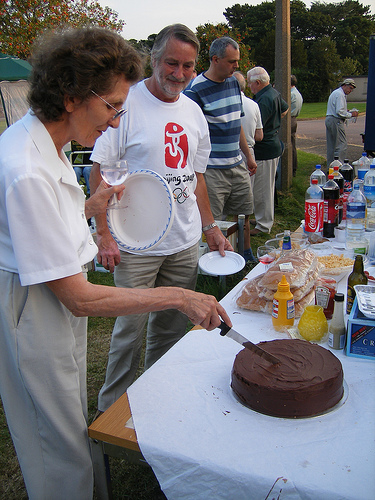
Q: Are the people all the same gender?
A: No, they are both male and female.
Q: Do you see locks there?
A: No, there are no locks.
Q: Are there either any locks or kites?
A: No, there are no locks or kites.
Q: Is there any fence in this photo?
A: No, there are no fences.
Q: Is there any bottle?
A: Yes, there is a bottle.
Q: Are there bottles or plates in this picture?
A: Yes, there is a bottle.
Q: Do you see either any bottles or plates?
A: Yes, there is a bottle.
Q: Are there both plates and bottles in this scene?
A: Yes, there are both a bottle and a plate.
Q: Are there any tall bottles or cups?
A: Yes, there is a tall bottle.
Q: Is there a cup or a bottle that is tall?
A: Yes, the bottle is tall.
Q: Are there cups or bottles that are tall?
A: Yes, the bottle is tall.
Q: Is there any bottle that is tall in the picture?
A: Yes, there is a tall bottle.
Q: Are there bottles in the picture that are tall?
A: Yes, there is a bottle that is tall.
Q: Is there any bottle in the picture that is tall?
A: Yes, there is a bottle that is tall.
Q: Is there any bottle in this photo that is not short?
A: Yes, there is a tall bottle.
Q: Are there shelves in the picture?
A: No, there are no shelves.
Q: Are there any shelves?
A: No, there are no shelves.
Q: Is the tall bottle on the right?
A: Yes, the bottle is on the right of the image.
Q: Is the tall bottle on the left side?
A: No, the bottle is on the right of the image.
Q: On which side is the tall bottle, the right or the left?
A: The bottle is on the right of the image.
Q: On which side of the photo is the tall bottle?
A: The bottle is on the right of the image.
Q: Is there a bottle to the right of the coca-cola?
A: Yes, there is a bottle to the right of the coca-cola.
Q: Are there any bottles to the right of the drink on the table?
A: Yes, there is a bottle to the right of the coca-cola.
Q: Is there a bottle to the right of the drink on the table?
A: Yes, there is a bottle to the right of the coca-cola.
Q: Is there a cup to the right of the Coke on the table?
A: No, there is a bottle to the right of the Coca Cola.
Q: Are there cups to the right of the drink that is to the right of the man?
A: No, there is a bottle to the right of the Coca Cola.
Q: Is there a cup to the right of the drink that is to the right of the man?
A: No, there is a bottle to the right of the Coca Cola.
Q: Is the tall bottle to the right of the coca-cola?
A: Yes, the bottle is to the right of the coca-cola.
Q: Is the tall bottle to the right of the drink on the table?
A: Yes, the bottle is to the right of the coca-cola.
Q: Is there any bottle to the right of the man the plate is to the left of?
A: Yes, there is a bottle to the right of the man.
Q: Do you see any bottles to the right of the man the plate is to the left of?
A: Yes, there is a bottle to the right of the man.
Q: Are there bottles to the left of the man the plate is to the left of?
A: No, the bottle is to the right of the man.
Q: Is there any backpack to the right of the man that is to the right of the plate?
A: No, there is a bottle to the right of the man.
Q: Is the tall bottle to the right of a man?
A: Yes, the bottle is to the right of a man.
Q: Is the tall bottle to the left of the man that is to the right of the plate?
A: No, the bottle is to the right of the man.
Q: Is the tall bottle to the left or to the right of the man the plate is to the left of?
A: The bottle is to the right of the man.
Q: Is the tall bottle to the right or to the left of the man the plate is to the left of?
A: The bottle is to the right of the man.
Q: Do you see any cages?
A: No, there are no cages.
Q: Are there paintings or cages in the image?
A: No, there are no cages or paintings.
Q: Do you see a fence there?
A: No, there are no fences.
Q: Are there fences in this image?
A: No, there are no fences.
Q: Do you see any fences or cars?
A: No, there are no fences or cars.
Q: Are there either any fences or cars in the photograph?
A: No, there are no fences or cars.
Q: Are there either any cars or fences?
A: No, there are no fences or cars.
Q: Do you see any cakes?
A: Yes, there is a cake.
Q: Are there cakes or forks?
A: Yes, there is a cake.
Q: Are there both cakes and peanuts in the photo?
A: No, there is a cake but no peanuts.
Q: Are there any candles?
A: No, there are no candles.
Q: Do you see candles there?
A: No, there are no candles.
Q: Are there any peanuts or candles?
A: No, there are no candles or peanuts.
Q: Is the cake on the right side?
A: Yes, the cake is on the right of the image.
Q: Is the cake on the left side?
A: No, the cake is on the right of the image.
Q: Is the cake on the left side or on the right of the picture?
A: The cake is on the right of the image.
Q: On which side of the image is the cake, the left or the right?
A: The cake is on the right of the image.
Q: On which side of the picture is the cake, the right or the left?
A: The cake is on the right of the image.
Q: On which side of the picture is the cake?
A: The cake is on the right of the image.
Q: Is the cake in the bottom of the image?
A: Yes, the cake is in the bottom of the image.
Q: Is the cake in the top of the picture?
A: No, the cake is in the bottom of the image.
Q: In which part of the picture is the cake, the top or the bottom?
A: The cake is in the bottom of the image.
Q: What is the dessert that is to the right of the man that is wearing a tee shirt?
A: The dessert is a cake.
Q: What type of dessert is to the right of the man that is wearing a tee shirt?
A: The dessert is a cake.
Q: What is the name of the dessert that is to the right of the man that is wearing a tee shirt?
A: The dessert is a cake.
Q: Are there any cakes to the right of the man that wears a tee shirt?
A: Yes, there is a cake to the right of the man.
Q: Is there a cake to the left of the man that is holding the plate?
A: No, the cake is to the right of the man.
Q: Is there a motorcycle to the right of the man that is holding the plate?
A: No, there is a cake to the right of the man.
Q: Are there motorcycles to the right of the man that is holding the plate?
A: No, there is a cake to the right of the man.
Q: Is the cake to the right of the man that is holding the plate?
A: Yes, the cake is to the right of the man.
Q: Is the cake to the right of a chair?
A: No, the cake is to the right of the man.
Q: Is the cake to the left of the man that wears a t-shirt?
A: No, the cake is to the right of the man.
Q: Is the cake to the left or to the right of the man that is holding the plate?
A: The cake is to the right of the man.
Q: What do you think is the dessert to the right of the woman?
A: The dessert is a cake.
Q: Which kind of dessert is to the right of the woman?
A: The dessert is a cake.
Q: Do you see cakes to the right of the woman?
A: Yes, there is a cake to the right of the woman.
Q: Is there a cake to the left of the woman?
A: No, the cake is to the right of the woman.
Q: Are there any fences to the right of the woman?
A: No, there is a cake to the right of the woman.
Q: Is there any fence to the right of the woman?
A: No, there is a cake to the right of the woman.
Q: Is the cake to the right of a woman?
A: Yes, the cake is to the right of a woman.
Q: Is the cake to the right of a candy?
A: No, the cake is to the right of a woman.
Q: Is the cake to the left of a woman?
A: No, the cake is to the right of a woman.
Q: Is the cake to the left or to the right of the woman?
A: The cake is to the right of the woman.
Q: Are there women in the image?
A: Yes, there is a woman.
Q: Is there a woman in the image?
A: Yes, there is a woman.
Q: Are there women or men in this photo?
A: Yes, there is a woman.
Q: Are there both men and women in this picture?
A: Yes, there are both a woman and a man.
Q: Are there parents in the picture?
A: No, there are no parents.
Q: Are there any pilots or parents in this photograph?
A: No, there are no parents or pilots.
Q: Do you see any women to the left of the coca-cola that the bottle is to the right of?
A: Yes, there is a woman to the left of the Cola.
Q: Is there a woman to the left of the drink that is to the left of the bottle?
A: Yes, there is a woman to the left of the Cola.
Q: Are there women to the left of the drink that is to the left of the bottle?
A: Yes, there is a woman to the left of the Cola.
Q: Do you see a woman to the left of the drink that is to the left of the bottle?
A: Yes, there is a woman to the left of the Cola.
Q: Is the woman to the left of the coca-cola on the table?
A: Yes, the woman is to the left of the coca-cola.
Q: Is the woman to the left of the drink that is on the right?
A: Yes, the woman is to the left of the coca-cola.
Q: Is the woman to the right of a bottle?
A: No, the woman is to the left of a bottle.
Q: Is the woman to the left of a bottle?
A: Yes, the woman is to the left of a bottle.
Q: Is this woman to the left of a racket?
A: No, the woman is to the left of a bottle.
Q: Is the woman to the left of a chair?
A: No, the woman is to the left of a man.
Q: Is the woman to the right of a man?
A: No, the woman is to the left of a man.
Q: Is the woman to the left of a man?
A: Yes, the woman is to the left of a man.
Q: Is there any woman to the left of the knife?
A: Yes, there is a woman to the left of the knife.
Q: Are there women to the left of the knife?
A: Yes, there is a woman to the left of the knife.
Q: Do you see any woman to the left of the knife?
A: Yes, there is a woman to the left of the knife.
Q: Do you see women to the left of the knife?
A: Yes, there is a woman to the left of the knife.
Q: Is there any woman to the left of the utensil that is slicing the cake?
A: Yes, there is a woman to the left of the knife.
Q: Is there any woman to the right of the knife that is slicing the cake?
A: No, the woman is to the left of the knife.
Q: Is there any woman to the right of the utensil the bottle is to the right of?
A: No, the woman is to the left of the knife.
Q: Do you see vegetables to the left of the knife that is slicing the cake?
A: No, there is a woman to the left of the knife.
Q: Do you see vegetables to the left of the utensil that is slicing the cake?
A: No, there is a woman to the left of the knife.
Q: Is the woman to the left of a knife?
A: Yes, the woman is to the left of a knife.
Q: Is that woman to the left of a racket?
A: No, the woman is to the left of a knife.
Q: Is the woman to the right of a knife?
A: No, the woman is to the left of a knife.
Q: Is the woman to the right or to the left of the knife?
A: The woman is to the left of the knife.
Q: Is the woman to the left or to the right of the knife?
A: The woman is to the left of the knife.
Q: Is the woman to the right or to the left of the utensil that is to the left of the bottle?
A: The woman is to the left of the knife.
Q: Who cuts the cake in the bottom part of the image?
A: The woman cuts the cake.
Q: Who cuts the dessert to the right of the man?
A: The woman cuts the cake.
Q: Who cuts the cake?
A: The woman cuts the cake.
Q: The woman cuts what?
A: The woman cuts the cake.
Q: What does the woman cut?
A: The woman cuts the cake.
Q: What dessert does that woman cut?
A: The woman cuts the cake.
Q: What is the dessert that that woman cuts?
A: The dessert is a cake.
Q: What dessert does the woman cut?
A: The woman cuts the cake.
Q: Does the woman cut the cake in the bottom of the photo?
A: Yes, the woman cuts the cake.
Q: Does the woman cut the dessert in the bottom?
A: Yes, the woman cuts the cake.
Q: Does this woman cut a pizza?
A: No, the woman cuts the cake.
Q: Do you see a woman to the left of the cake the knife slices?
A: Yes, there is a woman to the left of the cake.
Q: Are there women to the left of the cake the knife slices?
A: Yes, there is a woman to the left of the cake.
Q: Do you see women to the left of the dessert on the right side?
A: Yes, there is a woman to the left of the cake.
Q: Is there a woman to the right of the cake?
A: No, the woman is to the left of the cake.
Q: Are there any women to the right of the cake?
A: No, the woman is to the left of the cake.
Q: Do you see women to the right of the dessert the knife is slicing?
A: No, the woman is to the left of the cake.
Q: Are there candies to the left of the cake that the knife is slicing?
A: No, there is a woman to the left of the cake.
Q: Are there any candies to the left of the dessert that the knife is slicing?
A: No, there is a woman to the left of the cake.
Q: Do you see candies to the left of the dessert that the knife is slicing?
A: No, there is a woman to the left of the cake.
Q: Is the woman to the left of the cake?
A: Yes, the woman is to the left of the cake.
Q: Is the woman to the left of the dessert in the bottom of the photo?
A: Yes, the woman is to the left of the cake.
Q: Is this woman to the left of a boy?
A: No, the woman is to the left of the cake.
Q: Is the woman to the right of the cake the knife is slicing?
A: No, the woman is to the left of the cake.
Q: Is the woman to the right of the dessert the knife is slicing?
A: No, the woman is to the left of the cake.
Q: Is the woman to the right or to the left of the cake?
A: The woman is to the left of the cake.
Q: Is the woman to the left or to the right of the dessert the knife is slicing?
A: The woman is to the left of the cake.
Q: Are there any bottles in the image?
A: Yes, there is a bottle.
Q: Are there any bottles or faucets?
A: Yes, there is a bottle.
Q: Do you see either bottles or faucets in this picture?
A: Yes, there is a bottle.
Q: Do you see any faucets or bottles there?
A: Yes, there is a bottle.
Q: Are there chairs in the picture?
A: No, there are no chairs.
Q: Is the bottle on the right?
A: Yes, the bottle is on the right of the image.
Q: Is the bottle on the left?
A: No, the bottle is on the right of the image.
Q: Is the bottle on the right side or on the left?
A: The bottle is on the right of the image.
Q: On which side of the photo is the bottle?
A: The bottle is on the right of the image.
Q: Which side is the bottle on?
A: The bottle is on the right of the image.